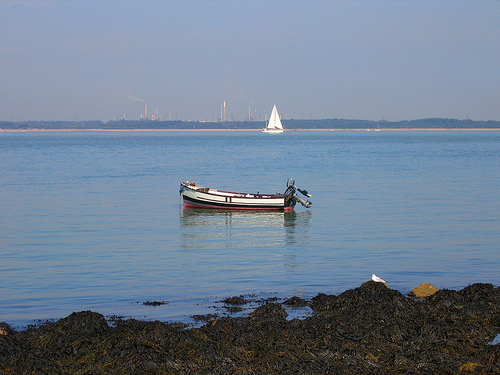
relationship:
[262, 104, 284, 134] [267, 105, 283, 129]
white sail has white sail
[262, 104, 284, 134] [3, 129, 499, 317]
white sail on water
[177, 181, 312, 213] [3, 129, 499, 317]
powerboat on water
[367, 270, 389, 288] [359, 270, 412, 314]
bird on rock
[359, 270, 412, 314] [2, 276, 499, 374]
rock on shoreline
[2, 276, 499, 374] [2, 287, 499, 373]
shoreline has seaweed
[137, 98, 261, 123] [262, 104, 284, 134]
power plant behind white sail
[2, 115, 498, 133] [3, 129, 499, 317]
shoreline across water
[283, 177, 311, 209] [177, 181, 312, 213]
engine on powerboat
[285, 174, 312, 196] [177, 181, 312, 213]
engine on powerboat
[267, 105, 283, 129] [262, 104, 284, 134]
sail on white sail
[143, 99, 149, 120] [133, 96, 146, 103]
smokestack makes smoke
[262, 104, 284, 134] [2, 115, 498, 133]
white sail near shoreline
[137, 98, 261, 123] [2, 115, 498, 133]
power plant on shoreline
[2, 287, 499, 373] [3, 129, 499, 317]
seaweed from water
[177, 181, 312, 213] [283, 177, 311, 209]
powerboat has engine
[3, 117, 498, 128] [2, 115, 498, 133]
landscaping on shoreline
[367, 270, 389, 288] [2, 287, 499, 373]
bird on top of seaweed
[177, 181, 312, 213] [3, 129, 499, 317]
powerboat in water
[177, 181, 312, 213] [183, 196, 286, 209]
powerboat has stripe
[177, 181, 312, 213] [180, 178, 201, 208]
powerboat has front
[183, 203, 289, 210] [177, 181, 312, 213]
stripe on bottom of powerboat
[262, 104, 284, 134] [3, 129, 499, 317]
white sail floating on water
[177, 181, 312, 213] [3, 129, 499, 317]
powerboat floating on water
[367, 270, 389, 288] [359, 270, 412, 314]
bird sitting on rock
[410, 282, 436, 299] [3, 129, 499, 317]
rock in water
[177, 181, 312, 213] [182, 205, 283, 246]
powerboat has reflection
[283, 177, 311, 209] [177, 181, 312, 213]
engine on back of powerboat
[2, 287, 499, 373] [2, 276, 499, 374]
seaweed on shoreline